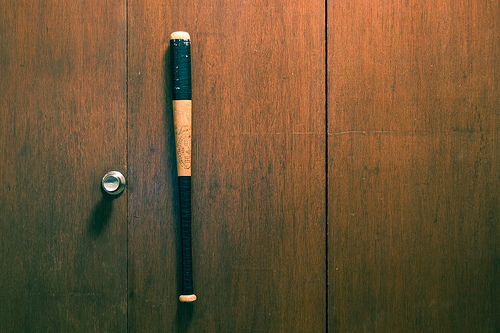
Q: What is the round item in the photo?
A: A doorknob.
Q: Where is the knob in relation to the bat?
A: To the left.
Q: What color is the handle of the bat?
A: Black.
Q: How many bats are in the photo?
A: One.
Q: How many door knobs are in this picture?
A: One.